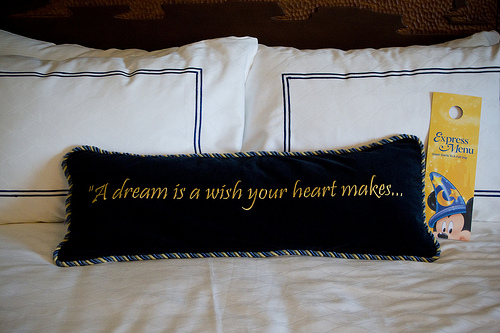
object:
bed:
[0, 0, 500, 333]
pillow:
[236, 29, 499, 222]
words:
[174, 183, 187, 199]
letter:
[91, 183, 107, 204]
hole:
[448, 105, 462, 120]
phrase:
[431, 152, 468, 160]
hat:
[425, 172, 465, 228]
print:
[431, 176, 443, 188]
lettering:
[88, 177, 403, 213]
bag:
[51, 134, 443, 268]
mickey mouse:
[427, 171, 474, 241]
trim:
[286, 69, 500, 81]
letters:
[469, 148, 474, 154]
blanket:
[0, 219, 500, 333]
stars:
[448, 189, 461, 201]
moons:
[436, 190, 455, 207]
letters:
[384, 184, 391, 196]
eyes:
[447, 221, 454, 234]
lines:
[282, 66, 500, 75]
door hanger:
[420, 91, 480, 242]